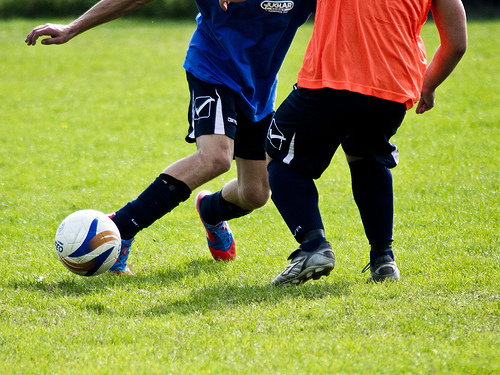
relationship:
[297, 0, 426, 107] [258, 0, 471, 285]
orange shirt on man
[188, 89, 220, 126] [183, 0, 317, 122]
print on shirt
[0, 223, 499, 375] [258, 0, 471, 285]
shadow of man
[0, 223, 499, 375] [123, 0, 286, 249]
shadow of player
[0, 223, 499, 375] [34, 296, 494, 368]
shadow on ground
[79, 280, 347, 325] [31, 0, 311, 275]
shadow of man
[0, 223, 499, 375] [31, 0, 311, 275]
shadow of man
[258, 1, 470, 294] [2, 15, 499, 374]
man on field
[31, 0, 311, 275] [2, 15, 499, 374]
man on field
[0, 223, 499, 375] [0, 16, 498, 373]
shadow on a ground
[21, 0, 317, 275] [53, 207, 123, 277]
man tussling for ball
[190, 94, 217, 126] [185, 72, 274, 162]
branding on shorts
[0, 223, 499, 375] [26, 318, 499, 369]
shadow cast on grass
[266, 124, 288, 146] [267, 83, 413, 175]
white check on black shorts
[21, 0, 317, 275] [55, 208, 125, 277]
man kicking ball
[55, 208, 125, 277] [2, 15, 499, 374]
ball on field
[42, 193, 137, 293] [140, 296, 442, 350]
ball on field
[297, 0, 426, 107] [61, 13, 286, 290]
orange shirt on player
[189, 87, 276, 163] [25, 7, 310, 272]
shorts on player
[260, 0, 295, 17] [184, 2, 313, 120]
logo on blue shirt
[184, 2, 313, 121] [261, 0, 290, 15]
blue shirt with letters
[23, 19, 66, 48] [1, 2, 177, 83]
hand in air